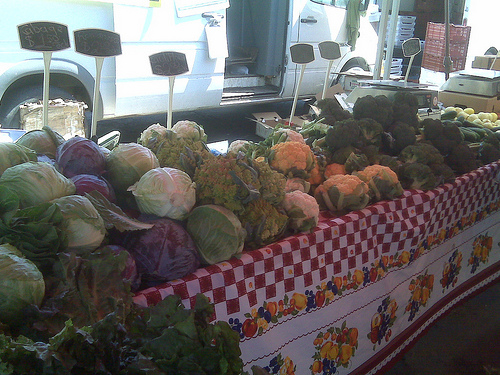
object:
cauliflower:
[311, 171, 375, 215]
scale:
[438, 68, 498, 98]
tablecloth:
[0, 161, 495, 373]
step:
[220, 72, 267, 87]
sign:
[71, 26, 122, 56]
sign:
[146, 50, 189, 77]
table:
[0, 84, 499, 366]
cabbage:
[53, 129, 202, 277]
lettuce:
[0, 139, 143, 321]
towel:
[343, 0, 365, 48]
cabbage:
[132, 169, 199, 222]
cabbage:
[105, 142, 161, 189]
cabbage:
[184, 204, 249, 266]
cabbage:
[0, 164, 74, 209]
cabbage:
[168, 119, 209, 153]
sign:
[17, 21, 70, 53]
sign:
[289, 44, 316, 63]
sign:
[314, 40, 339, 62]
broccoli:
[350, 90, 397, 128]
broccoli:
[389, 85, 420, 127]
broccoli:
[323, 115, 384, 153]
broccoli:
[418, 114, 465, 153]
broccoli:
[398, 156, 437, 192]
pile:
[319, 90, 480, 204]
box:
[242, 106, 327, 148]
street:
[359, 279, 499, 375]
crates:
[314, 44, 498, 194]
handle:
[196, 12, 225, 30]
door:
[98, 0, 231, 103]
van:
[0, 7, 393, 109]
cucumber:
[460, 128, 479, 141]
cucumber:
[474, 127, 492, 142]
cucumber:
[467, 141, 480, 160]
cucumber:
[438, 107, 461, 122]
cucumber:
[484, 126, 499, 140]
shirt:
[346, 0, 370, 52]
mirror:
[358, 0, 372, 15]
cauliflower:
[238, 131, 361, 216]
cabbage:
[1, 128, 250, 330]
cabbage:
[0, 126, 249, 371]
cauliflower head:
[309, 172, 372, 211]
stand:
[41, 50, 54, 127]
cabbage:
[134, 219, 196, 283]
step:
[223, 67, 281, 89]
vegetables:
[0, 91, 499, 374]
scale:
[437, 50, 499, 96]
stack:
[32, 120, 185, 273]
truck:
[16, 9, 387, 109]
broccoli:
[316, 86, 475, 190]